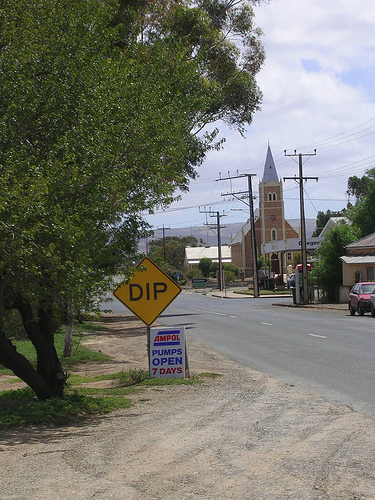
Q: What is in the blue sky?
A: Clouds.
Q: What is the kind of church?
A: Brick.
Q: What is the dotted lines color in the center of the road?
A: White.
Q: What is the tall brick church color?
A: Tan and brown.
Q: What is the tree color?
A: Green.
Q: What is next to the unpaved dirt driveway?
A: Sign.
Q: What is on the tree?
A: Leaves.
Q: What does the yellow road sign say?
A: Dip.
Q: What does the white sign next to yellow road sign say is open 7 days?
A: Ampol pumps.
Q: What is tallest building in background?
A: Church.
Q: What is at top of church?
A: Spire.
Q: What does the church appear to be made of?
A: Brick.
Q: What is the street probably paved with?
A: Asphalt.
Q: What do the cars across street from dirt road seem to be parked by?
A: Curb.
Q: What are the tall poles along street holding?
A: Power lines.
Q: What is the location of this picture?
A: Small town.